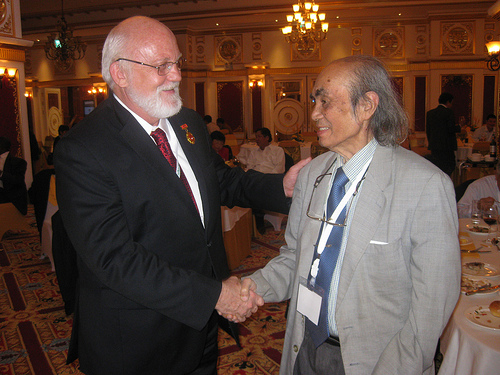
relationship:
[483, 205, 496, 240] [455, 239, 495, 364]
wine glass on table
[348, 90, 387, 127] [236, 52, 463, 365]
ear of person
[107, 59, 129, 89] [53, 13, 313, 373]
ear of person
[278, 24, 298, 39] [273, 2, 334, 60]
lights on chandelier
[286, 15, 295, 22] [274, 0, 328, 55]
light on chandelier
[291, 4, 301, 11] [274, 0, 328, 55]
light on chandelier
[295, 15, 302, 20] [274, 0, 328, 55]
light on chandelier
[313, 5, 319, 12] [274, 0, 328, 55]
light on chandelier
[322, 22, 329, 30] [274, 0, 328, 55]
light on chandelier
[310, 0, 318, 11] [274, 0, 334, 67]
light on chandelier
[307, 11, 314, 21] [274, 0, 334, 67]
light on chandelier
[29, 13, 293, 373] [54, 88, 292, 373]
man in suit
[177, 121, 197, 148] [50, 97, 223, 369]
medal on jacket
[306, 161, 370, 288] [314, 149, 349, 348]
lanyard with tag holder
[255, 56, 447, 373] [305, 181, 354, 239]
man wearing glasses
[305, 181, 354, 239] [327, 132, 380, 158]
glasses around neck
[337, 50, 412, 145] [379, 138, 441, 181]
hair falling on shoulder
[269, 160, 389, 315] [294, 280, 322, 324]
strap for tag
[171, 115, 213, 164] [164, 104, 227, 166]
badge on lapel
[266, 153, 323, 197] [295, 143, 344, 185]
hand holding shoulder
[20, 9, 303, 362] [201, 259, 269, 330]
man shaking hands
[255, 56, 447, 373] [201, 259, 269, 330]
man shaking hands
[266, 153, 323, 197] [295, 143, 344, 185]
hand on shoulder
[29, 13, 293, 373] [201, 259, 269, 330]
man shaking hands